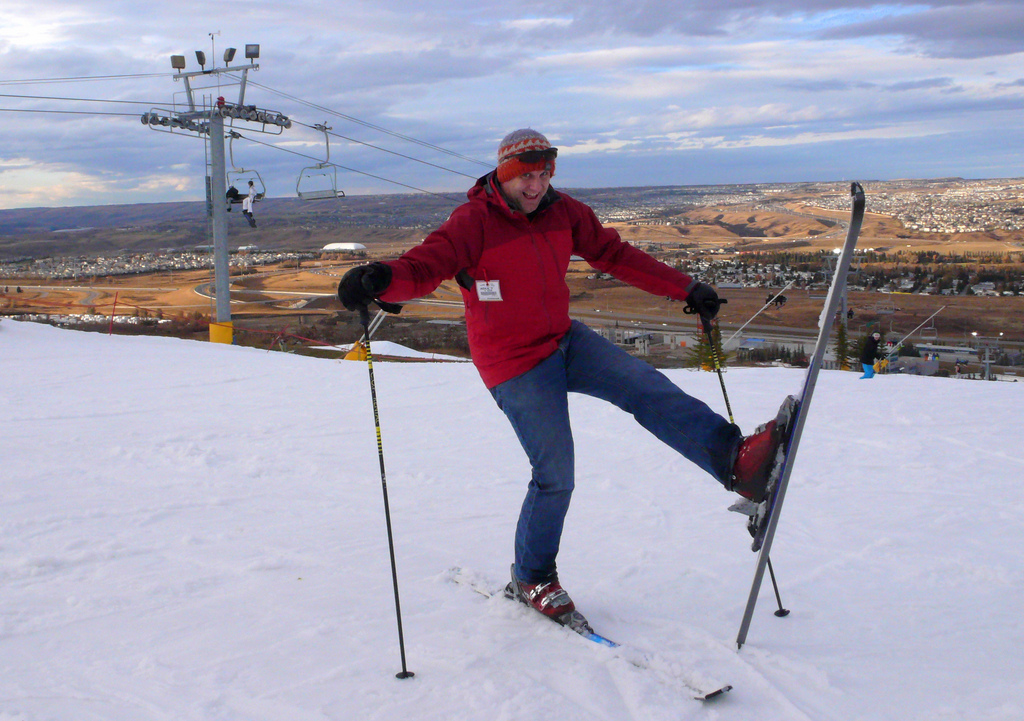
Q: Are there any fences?
A: No, there are no fences.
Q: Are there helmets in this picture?
A: No, there are no helmets.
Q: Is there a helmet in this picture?
A: No, there are no helmets.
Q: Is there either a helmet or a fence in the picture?
A: No, there are no helmets or fences.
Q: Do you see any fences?
A: No, there are no fences.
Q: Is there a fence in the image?
A: No, there are no fences.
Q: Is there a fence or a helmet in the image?
A: No, there are no fences or helmets.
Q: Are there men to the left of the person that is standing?
A: Yes, there is a man to the left of the person.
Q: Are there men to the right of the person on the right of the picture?
A: No, the man is to the left of the person.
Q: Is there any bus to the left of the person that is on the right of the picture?
A: No, there is a man to the left of the person.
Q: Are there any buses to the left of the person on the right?
A: No, there is a man to the left of the person.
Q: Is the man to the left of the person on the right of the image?
A: Yes, the man is to the left of the person.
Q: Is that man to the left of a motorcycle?
A: No, the man is to the left of the person.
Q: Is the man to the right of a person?
A: No, the man is to the left of a person.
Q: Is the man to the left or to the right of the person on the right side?
A: The man is to the left of the person.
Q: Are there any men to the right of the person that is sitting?
A: Yes, there is a man to the right of the person.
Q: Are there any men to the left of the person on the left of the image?
A: No, the man is to the right of the person.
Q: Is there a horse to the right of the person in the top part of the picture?
A: No, there is a man to the right of the person.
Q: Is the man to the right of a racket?
A: No, the man is to the right of a person.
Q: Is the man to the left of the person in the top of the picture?
A: No, the man is to the right of the person.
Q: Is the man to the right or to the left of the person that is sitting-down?
A: The man is to the right of the person.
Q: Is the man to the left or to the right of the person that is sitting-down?
A: The man is to the right of the person.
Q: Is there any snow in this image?
A: Yes, there is snow.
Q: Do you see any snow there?
A: Yes, there is snow.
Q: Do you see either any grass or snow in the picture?
A: Yes, there is snow.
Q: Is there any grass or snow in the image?
A: Yes, there is snow.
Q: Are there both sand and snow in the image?
A: No, there is snow but no sand.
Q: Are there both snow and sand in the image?
A: No, there is snow but no sand.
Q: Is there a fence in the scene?
A: No, there are no fences.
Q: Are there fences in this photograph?
A: No, there are no fences.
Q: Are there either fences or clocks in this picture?
A: No, there are no fences or clocks.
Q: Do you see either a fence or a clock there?
A: No, there are no fences or clocks.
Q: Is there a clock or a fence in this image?
A: No, there are no fences or clocks.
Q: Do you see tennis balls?
A: No, there are no tennis balls.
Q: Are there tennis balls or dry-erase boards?
A: No, there are no tennis balls or dry-erase boards.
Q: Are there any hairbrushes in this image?
A: No, there are no hairbrushes.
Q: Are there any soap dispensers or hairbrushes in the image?
A: No, there are no hairbrushes or soap dispensers.